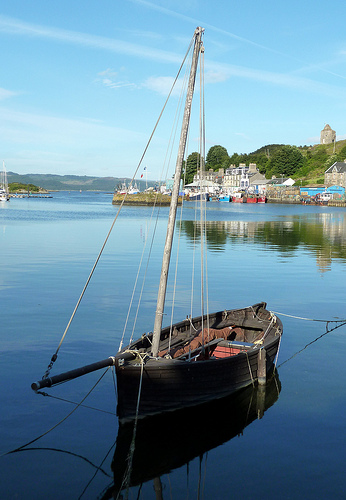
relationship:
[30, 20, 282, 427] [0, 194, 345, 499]
ship in bay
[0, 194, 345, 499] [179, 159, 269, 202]
bay by town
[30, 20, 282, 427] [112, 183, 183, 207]
ship by island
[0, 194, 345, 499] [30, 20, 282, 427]
bay with a ship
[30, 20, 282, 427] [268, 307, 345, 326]
ship held with a rope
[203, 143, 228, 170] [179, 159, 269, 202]
tree behind town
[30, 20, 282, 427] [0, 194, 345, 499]
ship floating in bay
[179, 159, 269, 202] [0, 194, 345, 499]
town by bay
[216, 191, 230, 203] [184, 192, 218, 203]
boat at dock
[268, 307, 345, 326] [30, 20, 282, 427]
rope on ship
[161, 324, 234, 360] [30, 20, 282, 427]
sail on ship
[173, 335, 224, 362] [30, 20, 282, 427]
oar on ship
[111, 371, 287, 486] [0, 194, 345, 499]
shadow on bay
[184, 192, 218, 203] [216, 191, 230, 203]
dock by boat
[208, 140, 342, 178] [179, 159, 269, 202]
hill by town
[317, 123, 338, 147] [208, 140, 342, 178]
structure on hill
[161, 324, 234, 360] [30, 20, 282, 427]
sail in ship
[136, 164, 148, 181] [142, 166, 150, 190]
flag on a post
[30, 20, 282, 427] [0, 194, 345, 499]
ship in calm bay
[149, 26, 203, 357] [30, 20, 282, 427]
mast on ship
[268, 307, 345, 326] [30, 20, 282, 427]
rope tied to ship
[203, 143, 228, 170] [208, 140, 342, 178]
tree on hill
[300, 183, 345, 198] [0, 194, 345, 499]
building near bay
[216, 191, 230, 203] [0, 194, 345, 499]
boat on bay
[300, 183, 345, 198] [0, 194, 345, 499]
building by bay